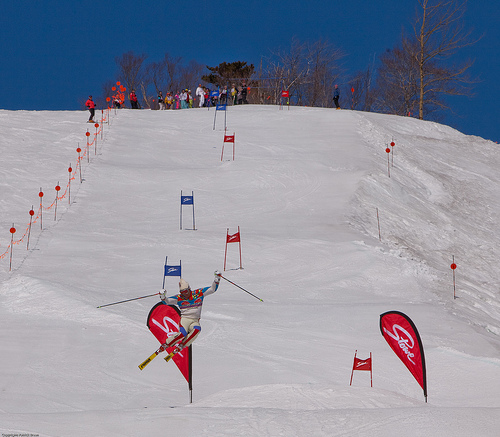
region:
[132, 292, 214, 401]
red flag in white snow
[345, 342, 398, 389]
red flag in white snow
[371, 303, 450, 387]
red flag in white snow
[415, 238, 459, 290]
red flag in white snow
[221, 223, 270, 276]
red flag in white snow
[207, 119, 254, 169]
red flag in white snow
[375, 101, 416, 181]
red flag in white snow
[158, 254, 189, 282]
blue flag in white snow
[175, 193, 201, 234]
blue flag in white snow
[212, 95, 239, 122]
Blue marker sticking out of snow.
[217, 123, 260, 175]
Red flag sticking out of snow.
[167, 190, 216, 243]
Blue marker sticking out of snow.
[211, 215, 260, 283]
Red marker sticking out of snow.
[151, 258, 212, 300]
Blue marker sticking out of snow.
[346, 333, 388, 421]
Red marker sticking out of snow.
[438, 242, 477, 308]
Red marker sticking out of snow.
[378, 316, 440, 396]
White writing on flag in snow.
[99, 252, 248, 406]
Person on skis jumping.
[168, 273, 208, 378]
Person wearing red, white, and blue suit.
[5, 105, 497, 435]
a snowy hill side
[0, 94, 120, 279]
a boundary line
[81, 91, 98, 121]
a skier on slope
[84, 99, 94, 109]
a red winter coat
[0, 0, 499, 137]
a deep blue sky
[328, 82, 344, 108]
a person standing on top of hill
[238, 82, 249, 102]
a person standing on top of hill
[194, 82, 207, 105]
a person standing on top of hill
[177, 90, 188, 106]
a person standing on top of hill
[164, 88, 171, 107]
a person standing on top of hill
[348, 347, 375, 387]
a red flag obstacle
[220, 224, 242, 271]
a red flag obstacle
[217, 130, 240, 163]
a red flag obstacle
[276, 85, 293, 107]
a red flag obstacle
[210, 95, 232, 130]
a blue flag obstacle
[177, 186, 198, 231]
a blue flag obstacle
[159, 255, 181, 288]
a blue flag obstacle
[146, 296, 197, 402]
a red advertising flag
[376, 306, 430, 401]
a red advertising flag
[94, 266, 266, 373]
a snow skier in air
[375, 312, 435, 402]
red and black flag in the ground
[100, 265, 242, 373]
a skier jumped up into the air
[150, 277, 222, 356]
red blue and white ski uniform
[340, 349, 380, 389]
red flag on the ski slope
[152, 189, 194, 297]
two blue flags on the hill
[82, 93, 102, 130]
person in orange coming down the hill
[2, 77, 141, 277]
an orange fence down the hill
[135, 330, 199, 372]
yellow ski's in the air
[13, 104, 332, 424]
a trail down the hill of snow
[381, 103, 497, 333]
rough snow on the side of the track